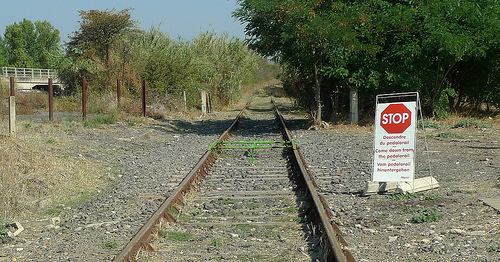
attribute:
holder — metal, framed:
[373, 93, 434, 196]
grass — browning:
[3, 102, 153, 235]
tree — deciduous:
[233, 0, 368, 132]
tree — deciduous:
[21, 21, 62, 96]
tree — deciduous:
[411, 0, 472, 123]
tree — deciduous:
[4, 21, 32, 66]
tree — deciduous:
[144, 56, 170, 98]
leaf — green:
[310, 22, 318, 31]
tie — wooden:
[199, 173, 291, 177]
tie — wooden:
[183, 213, 301, 219]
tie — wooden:
[169, 221, 303, 227]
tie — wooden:
[214, 164, 289, 167]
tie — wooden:
[195, 196, 300, 200]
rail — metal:
[0, 67, 58, 76]